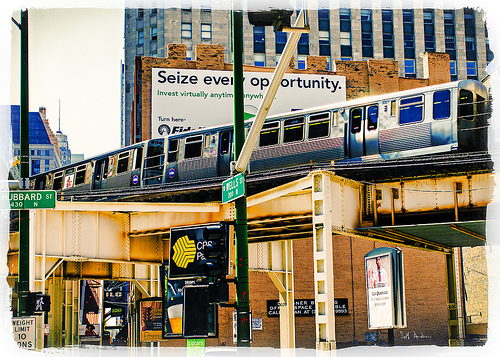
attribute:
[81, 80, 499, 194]
train — silver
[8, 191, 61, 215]
street signs — green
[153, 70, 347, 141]
large sign — white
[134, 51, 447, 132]
building — large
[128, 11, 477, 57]
offices — large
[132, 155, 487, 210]
tracks — grey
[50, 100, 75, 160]
building — brown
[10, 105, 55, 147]
roof — blue, slanted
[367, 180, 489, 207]
beems — tan